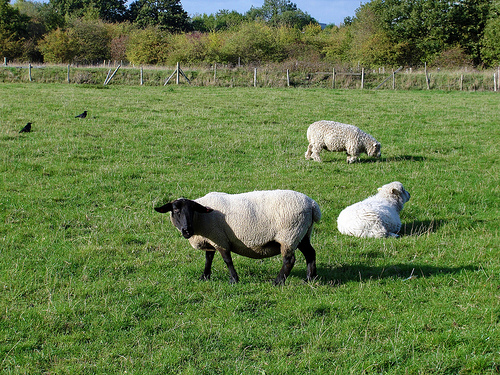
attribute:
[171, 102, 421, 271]
sheep — three, white haired, white, grazing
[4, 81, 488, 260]
grass — green, well maintained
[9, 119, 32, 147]
bird — black, small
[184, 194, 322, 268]
sheep — thick haired, small, beautiful, standing, looking left, black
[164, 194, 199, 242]
head — black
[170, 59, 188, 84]
poles — dried up, wooden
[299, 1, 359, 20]
sky — clear, blue, bright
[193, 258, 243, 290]
legs — black, strong, short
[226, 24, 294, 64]
shrub — green, bushy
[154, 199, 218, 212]
ears — black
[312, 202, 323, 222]
tail — white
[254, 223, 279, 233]
wool — white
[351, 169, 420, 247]
animal — laying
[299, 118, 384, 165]
animal — eating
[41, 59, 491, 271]
field — grassy, grass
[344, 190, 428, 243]
sheep — laying down, laying, resting, white, looking right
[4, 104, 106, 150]
birds — black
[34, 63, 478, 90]
fence — wooden, wire, metal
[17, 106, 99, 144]
crows — black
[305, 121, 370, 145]
sheep — eating, white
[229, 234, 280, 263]
belly — bulky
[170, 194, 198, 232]
face — black